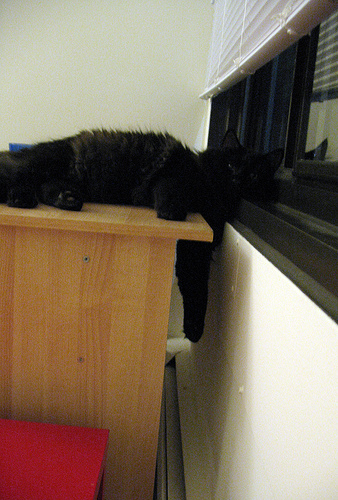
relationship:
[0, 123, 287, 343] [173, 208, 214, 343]
cat has a paw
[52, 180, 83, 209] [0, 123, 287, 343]
foot of a cat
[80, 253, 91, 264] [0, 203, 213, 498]
screw on desk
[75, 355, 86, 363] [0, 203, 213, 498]
screw on desk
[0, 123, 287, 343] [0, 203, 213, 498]
cat laying on desk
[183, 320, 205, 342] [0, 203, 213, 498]
paw hanging off desk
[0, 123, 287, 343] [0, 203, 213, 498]
cat has a paw hanging off desk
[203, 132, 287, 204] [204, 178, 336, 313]
head on window ledge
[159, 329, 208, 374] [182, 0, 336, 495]
vent on wall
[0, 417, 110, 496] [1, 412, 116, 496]
table next to desk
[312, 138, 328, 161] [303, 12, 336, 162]
ear reflected on window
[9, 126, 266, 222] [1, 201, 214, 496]
cat sleeping on dresser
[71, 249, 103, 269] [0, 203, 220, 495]
screw in wood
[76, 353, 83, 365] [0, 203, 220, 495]
screw in wood